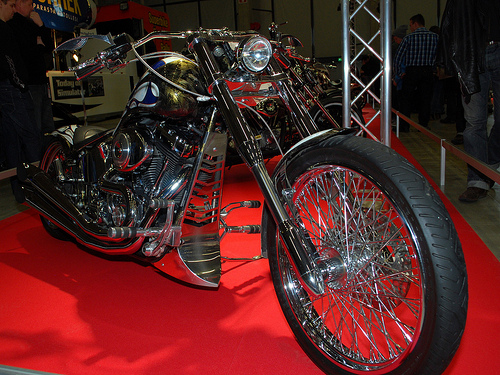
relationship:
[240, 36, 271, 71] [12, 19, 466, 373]
headlight of motorcycle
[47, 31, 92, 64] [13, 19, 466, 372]
mirror on bike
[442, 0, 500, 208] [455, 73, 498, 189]
man wearing pants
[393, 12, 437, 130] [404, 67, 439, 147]
man wearing pants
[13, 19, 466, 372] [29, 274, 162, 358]
bike on red surface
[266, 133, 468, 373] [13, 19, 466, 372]
front tire on bike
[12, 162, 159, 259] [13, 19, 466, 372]
exhaust on bike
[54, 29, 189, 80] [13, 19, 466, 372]
metal handle on bike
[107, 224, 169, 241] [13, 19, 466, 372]
stand on bike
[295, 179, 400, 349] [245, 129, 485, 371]
silver spokes in tire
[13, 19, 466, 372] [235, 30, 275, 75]
bike has headlight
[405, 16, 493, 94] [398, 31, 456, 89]
man wears shirt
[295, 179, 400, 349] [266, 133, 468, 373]
silver spokes on front tire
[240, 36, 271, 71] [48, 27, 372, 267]
headlight on front of bike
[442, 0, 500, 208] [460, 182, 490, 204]
man wears black shoe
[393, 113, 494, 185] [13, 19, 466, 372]
railing in front of bike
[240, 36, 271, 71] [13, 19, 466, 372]
headlight on bike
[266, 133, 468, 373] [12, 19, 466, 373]
front tire on motorcycle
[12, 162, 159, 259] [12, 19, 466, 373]
exhaust on motorcycle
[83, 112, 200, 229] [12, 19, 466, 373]
engine on motorcycle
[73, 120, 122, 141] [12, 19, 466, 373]
seat on motorcycle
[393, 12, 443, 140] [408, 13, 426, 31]
man has head